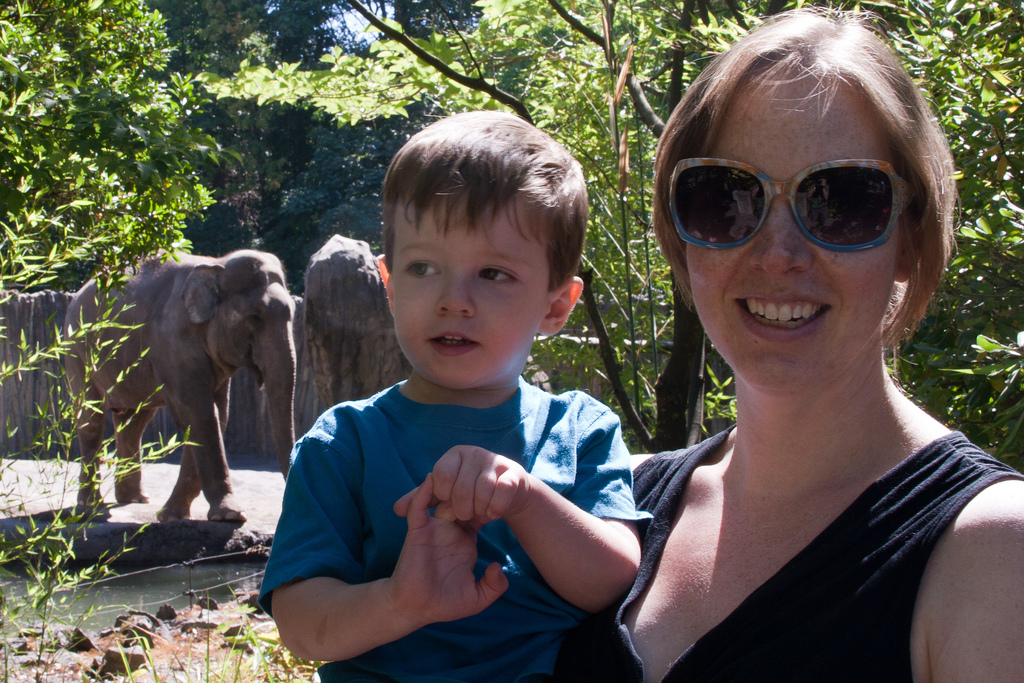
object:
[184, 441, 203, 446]
leaf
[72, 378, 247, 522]
stem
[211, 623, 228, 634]
leaf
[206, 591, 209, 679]
stem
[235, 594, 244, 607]
leaf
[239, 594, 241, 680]
stem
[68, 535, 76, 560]
leaf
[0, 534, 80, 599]
stem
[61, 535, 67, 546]
leaf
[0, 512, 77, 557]
stem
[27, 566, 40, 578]
leaf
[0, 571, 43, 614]
stem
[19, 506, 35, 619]
stem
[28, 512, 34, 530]
leaf